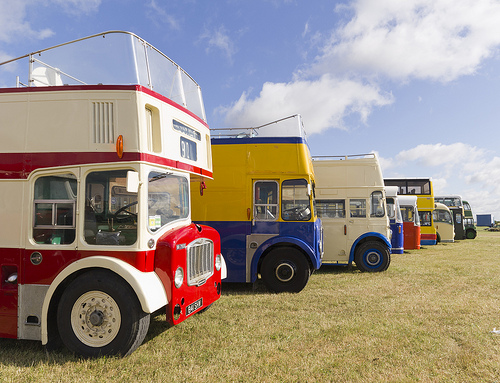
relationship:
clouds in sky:
[332, 6, 496, 76] [248, 13, 446, 92]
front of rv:
[208, 139, 321, 292] [204, 117, 320, 290]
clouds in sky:
[0, 0, 57, 47] [0, 0, 498, 220]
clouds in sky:
[238, 72, 360, 143] [0, 0, 498, 220]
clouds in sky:
[332, 6, 496, 76] [0, 0, 498, 220]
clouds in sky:
[0, 1, 498, 223] [0, 0, 498, 220]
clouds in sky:
[226, 4, 498, 119] [0, 0, 498, 220]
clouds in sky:
[314, 7, 369, 111] [0, 0, 498, 220]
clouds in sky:
[53, 1, 100, 18] [0, 0, 498, 220]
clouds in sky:
[192, 20, 237, 69] [0, 0, 498, 220]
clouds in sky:
[378, 140, 498, 207] [0, 0, 498, 220]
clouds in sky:
[139, 4, 192, 53] [0, 0, 498, 220]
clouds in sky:
[378, 140, 498, 220] [0, 0, 498, 220]